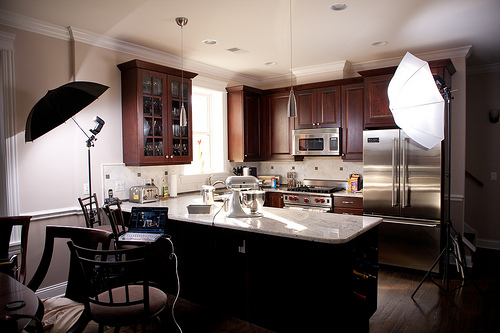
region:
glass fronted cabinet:
[116, 60, 201, 171]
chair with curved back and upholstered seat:
[60, 236, 178, 322]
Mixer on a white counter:
[215, 170, 281, 218]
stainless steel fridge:
[360, 130, 437, 260]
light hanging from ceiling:
[171, 10, 192, 130]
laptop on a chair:
[113, 202, 174, 257]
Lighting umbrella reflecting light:
[15, 77, 117, 197]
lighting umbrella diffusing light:
[376, 42, 471, 240]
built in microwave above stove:
[287, 125, 347, 161]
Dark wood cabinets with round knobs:
[215, 78, 372, 161]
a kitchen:
[43, 45, 460, 332]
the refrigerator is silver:
[353, 125, 448, 286]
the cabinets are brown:
[110, 55, 447, 166]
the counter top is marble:
[103, 162, 388, 267]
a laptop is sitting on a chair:
[75, 187, 202, 282]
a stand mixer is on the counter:
[177, 158, 292, 234]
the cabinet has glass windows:
[116, 53, 210, 174]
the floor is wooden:
[311, 237, 497, 329]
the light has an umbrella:
[18, 63, 150, 262]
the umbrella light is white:
[380, 51, 499, 264]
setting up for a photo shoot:
[217, 48, 447, 233]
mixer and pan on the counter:
[179, 169, 301, 237]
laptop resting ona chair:
[111, 195, 182, 267]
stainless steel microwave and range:
[278, 127, 350, 215]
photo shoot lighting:
[31, 63, 129, 230]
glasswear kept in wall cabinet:
[113, 54, 210, 177]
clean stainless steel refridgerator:
[357, 131, 451, 278]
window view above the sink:
[120, 60, 278, 190]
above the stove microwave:
[284, 126, 362, 176]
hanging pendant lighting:
[163, 12, 315, 157]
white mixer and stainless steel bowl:
[212, 172, 274, 230]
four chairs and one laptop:
[0, 176, 207, 325]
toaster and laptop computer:
[116, 176, 178, 254]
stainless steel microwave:
[291, 127, 343, 160]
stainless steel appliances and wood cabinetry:
[277, 86, 449, 306]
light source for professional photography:
[382, 69, 482, 314]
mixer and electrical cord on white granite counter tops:
[209, 174, 388, 301]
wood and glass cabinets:
[120, 67, 202, 176]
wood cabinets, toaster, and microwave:
[117, 67, 364, 211]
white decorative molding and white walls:
[3, 71, 104, 274]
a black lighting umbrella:
[16, 55, 111, 156]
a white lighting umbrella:
[382, 73, 473, 242]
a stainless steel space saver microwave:
[285, 122, 347, 169]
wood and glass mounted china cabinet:
[118, 77, 198, 169]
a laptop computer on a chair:
[108, 192, 189, 282]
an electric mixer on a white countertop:
[203, 170, 279, 236]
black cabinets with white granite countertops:
[263, 203, 380, 320]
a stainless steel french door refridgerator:
[355, 112, 447, 279]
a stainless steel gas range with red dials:
[282, 175, 340, 213]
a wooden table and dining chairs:
[0, 211, 138, 329]